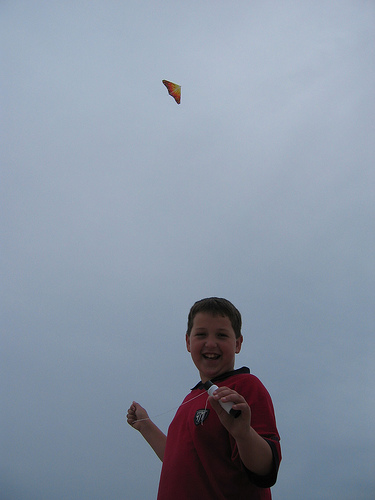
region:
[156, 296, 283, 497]
boy in red t-shirt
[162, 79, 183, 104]
orange yellow and blue kite in the sky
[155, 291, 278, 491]
boy with red t-shirt flying kite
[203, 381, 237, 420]
white thread in the left hand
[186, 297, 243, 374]
head of a white boy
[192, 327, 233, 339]
two closed eyes of a boy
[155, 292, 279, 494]
boy smilingly to camera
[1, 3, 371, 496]
blue clear sky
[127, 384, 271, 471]
two hands of a boy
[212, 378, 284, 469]
left hand holding a white thread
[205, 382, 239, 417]
The spool of the string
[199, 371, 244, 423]
Holding the handle of the kite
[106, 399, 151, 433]
The sting in his hand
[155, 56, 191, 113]
A kite in the air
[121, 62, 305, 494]
The boy flying a kite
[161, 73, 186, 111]
The kite is yellow red and orange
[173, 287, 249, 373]
The boy is smiling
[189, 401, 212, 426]
Logo on the shirt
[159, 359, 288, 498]
A red tee shirt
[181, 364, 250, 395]
The black shirt collar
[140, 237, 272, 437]
The boy is flying a kite.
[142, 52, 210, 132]
The kite is in the sky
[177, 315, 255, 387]
The boy is laughing.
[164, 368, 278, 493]
The boy is wearing a red shirt.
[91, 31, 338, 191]
The sky is clear and blue.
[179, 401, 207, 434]
The shirt has a black logo on it.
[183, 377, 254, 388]
The collar of the shirt is black.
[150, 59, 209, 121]
The kite is yellow and orange.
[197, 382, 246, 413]
The boy is holding the kite roller in his hand.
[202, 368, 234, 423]
The string on the kite is white.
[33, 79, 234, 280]
the kite is flying high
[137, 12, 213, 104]
the kite is flying high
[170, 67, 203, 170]
the kite is flying high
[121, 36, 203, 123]
the kite is flying high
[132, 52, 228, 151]
the kite is flying high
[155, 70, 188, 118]
yellow and orange kite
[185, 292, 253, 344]
boy has brown hair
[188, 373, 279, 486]
boy has red shirt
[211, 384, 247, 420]
boy holds spool of thread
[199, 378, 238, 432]
kite string is white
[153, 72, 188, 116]
kite far away from boy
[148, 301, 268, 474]
boy is smiling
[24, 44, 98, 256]
sky is grey and overcast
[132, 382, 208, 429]
kite string is thin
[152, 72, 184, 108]
kite has red edges